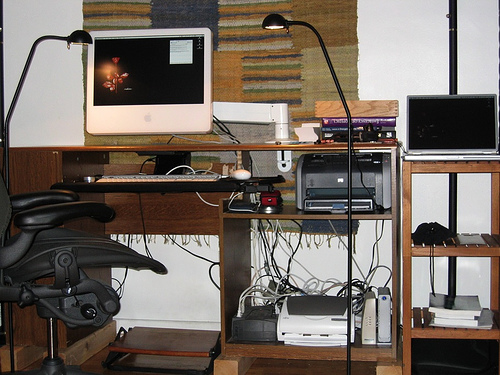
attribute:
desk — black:
[1, 139, 498, 373]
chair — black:
[1, 165, 177, 372]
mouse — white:
[221, 160, 259, 187]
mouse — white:
[230, 167, 251, 183]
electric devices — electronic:
[88, 25, 403, 296]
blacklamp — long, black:
[261, 11, 358, 373]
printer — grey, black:
[266, 129, 402, 222]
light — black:
[3, 28, 93, 194]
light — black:
[260, 11, 358, 118]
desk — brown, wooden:
[8, 140, 403, 374]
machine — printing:
[275, 290, 360, 346]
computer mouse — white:
[223, 163, 264, 183]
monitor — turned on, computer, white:
[85, 26, 213, 135]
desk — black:
[67, 41, 457, 352]